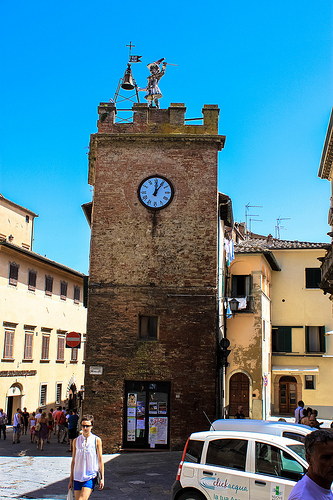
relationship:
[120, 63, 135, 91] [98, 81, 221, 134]
bell on top of tower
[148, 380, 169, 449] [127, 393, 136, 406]
door covered in flyer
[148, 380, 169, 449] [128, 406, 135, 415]
door covered in flyer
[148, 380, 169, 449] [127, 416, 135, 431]
door covered in flyer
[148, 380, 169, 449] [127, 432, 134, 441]
door covered in flyer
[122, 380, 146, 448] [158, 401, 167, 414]
door covered in flyer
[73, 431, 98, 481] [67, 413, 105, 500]
shirt of woman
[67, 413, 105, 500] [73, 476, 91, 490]
woman and shorts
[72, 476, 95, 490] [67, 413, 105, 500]
blue shorts of woman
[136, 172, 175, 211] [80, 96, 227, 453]
clock on a tower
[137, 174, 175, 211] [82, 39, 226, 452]
clock on tower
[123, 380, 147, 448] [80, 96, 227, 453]
door on tower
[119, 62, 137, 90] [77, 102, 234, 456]
bell on top of building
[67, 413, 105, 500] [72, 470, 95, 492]
woman wearing blue shorts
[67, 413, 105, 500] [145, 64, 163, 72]
woman wearing sunglasses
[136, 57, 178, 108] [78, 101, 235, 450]
pirate on top of building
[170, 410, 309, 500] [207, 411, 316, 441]
car next to white car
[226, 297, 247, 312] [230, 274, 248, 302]
linen hanging out window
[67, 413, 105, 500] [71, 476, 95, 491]
woman in shorts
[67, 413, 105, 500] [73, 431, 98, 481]
woman in shirt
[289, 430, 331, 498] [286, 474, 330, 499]
man wearing t-shirt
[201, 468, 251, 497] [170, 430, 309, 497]
name on car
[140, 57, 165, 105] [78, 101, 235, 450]
pirate on top of building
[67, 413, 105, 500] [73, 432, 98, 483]
woman walking in shirt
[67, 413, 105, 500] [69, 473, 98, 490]
woman walking in blue shorts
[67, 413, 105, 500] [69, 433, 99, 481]
woman wearing white top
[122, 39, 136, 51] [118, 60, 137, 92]
cross attached to bell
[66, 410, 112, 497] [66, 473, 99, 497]
woman wears blue shorts